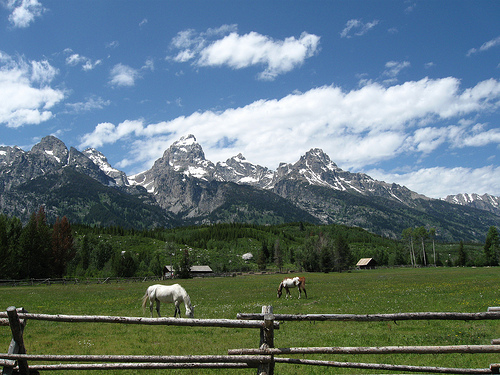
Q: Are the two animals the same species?
A: Yes, all the animals are horses.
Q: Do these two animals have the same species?
A: Yes, all the animals are horses.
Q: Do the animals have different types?
A: No, all the animals are horses.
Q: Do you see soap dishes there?
A: No, there are no soap dishes.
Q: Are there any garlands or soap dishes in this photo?
A: No, there are no soap dishes or garlands.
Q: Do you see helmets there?
A: No, there are no helmets.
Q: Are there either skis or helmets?
A: No, there are no helmets or skis.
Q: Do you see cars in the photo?
A: No, there are no cars.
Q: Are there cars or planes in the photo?
A: No, there are no cars or planes.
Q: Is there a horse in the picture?
A: Yes, there is a horse.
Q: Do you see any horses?
A: Yes, there is a horse.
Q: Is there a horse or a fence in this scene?
A: Yes, there is a horse.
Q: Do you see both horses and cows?
A: No, there is a horse but no cows.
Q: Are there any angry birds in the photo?
A: No, there are no angry birds.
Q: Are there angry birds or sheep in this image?
A: No, there are no angry birds or sheep.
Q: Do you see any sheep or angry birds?
A: No, there are no angry birds or sheep.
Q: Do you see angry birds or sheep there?
A: No, there are no angry birds or sheep.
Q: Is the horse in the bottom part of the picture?
A: Yes, the horse is in the bottom of the image.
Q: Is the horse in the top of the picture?
A: No, the horse is in the bottom of the image.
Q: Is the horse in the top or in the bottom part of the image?
A: The horse is in the bottom of the image.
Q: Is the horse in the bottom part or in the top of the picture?
A: The horse is in the bottom of the image.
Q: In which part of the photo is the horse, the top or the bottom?
A: The horse is in the bottom of the image.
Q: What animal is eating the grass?
A: The horse is eating the grass.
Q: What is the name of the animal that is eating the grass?
A: The animal is a horse.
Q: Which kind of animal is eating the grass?
A: The animal is a horse.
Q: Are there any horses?
A: Yes, there is a horse.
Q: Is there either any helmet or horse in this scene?
A: Yes, there is a horse.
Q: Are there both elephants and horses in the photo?
A: No, there is a horse but no elephants.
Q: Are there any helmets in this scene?
A: No, there are no helmets.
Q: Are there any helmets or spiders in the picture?
A: No, there are no helmets or spiders.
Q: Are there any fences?
A: Yes, there is a fence.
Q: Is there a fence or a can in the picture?
A: Yes, there is a fence.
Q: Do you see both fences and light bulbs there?
A: No, there is a fence but no light bulbs.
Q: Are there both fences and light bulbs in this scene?
A: No, there is a fence but no light bulbs.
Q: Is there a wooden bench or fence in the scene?
A: Yes, there is a wood fence.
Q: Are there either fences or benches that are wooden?
A: Yes, the fence is wooden.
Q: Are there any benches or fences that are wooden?
A: Yes, the fence is wooden.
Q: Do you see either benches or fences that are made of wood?
A: Yes, the fence is made of wood.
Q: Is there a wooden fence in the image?
A: Yes, there is a wood fence.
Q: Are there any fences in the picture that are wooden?
A: Yes, there is a fence that is wooden.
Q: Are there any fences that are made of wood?
A: Yes, there is a fence that is made of wood.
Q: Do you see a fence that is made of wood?
A: Yes, there is a fence that is made of wood.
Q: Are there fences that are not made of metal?
A: Yes, there is a fence that is made of wood.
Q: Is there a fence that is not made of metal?
A: Yes, there is a fence that is made of wood.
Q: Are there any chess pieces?
A: No, there are no chess pieces.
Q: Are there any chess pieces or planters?
A: No, there are no chess pieces or planters.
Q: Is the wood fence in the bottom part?
A: Yes, the fence is in the bottom of the image.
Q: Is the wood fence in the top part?
A: No, the fence is in the bottom of the image.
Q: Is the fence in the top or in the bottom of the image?
A: The fence is in the bottom of the image.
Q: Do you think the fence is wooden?
A: Yes, the fence is wooden.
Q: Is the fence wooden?
A: Yes, the fence is wooden.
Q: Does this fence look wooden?
A: Yes, the fence is wooden.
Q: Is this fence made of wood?
A: Yes, the fence is made of wood.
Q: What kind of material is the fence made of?
A: The fence is made of wood.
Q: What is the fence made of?
A: The fence is made of wood.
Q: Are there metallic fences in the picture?
A: No, there is a fence but it is wooden.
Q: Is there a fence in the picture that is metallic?
A: No, there is a fence but it is wooden.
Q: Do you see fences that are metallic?
A: No, there is a fence but it is wooden.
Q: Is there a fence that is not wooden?
A: No, there is a fence but it is wooden.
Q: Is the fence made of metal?
A: No, the fence is made of wood.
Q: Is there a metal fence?
A: No, there is a fence but it is made of wood.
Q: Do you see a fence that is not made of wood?
A: No, there is a fence but it is made of wood.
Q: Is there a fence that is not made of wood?
A: No, there is a fence but it is made of wood.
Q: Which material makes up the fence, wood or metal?
A: The fence is made of wood.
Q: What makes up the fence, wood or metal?
A: The fence is made of wood.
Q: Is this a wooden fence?
A: Yes, this is a wooden fence.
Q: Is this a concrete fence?
A: No, this is a wooden fence.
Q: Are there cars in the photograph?
A: No, there are no cars.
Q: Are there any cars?
A: No, there are no cars.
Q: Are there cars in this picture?
A: No, there are no cars.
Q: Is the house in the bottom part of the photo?
A: Yes, the house is in the bottom of the image.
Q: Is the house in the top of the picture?
A: No, the house is in the bottom of the image.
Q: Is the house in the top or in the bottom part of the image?
A: The house is in the bottom of the image.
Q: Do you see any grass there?
A: Yes, there is grass.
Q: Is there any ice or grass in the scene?
A: Yes, there is grass.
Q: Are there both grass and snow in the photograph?
A: Yes, there are both grass and snow.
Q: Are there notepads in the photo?
A: No, there are no notepads.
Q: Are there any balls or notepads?
A: No, there are no notepads or balls.